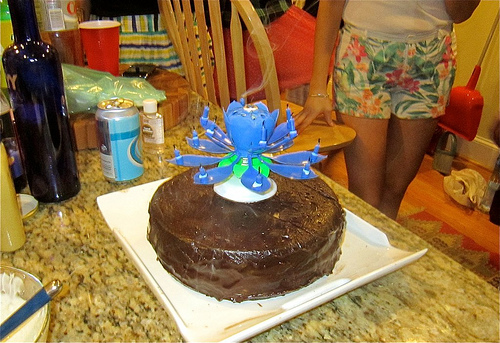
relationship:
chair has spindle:
[159, 1, 357, 155] [208, 0, 230, 114]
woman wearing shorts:
[293, 0, 480, 221] [333, 23, 458, 119]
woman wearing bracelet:
[293, 0, 480, 221] [306, 93, 329, 96]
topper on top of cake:
[166, 98, 328, 203] [148, 159, 344, 303]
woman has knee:
[293, 0, 480, 221] [387, 182, 404, 202]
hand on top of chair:
[290, 97, 334, 133] [159, 1, 357, 155]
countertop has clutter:
[1, 90, 499, 343] [1, 1, 166, 343]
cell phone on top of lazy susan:
[121, 64, 155, 78] [67, 64, 191, 150]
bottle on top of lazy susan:
[44, 0, 83, 67] [67, 64, 191, 150]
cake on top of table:
[148, 159, 344, 303] [1, 90, 499, 343]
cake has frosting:
[148, 159, 344, 303] [149, 158, 346, 302]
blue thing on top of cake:
[166, 98, 328, 203] [148, 159, 344, 303]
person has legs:
[293, 0, 480, 221] [335, 110, 438, 219]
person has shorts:
[293, 0, 480, 221] [333, 23, 458, 119]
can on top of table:
[96, 97, 141, 183] [1, 90, 499, 343]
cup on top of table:
[80, 21, 120, 78] [1, 90, 499, 343]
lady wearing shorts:
[293, 0, 480, 221] [333, 23, 458, 119]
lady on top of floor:
[293, 0, 480, 221] [311, 83, 500, 256]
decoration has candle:
[166, 98, 328, 203] [172, 145, 178, 158]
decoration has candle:
[166, 98, 328, 203] [193, 128, 196, 136]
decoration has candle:
[166, 98, 328, 203] [258, 168, 260, 176]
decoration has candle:
[166, 98, 328, 203] [307, 157, 311, 167]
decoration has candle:
[166, 98, 328, 203] [285, 104, 290, 119]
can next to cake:
[96, 97, 141, 183] [148, 159, 344, 303]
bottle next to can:
[140, 99, 164, 154] [96, 97, 141, 183]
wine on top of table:
[2, 0, 80, 202] [1, 90, 499, 343]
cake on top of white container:
[148, 159, 344, 303] [97, 175, 428, 342]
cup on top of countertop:
[80, 21, 120, 78] [1, 90, 499, 343]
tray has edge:
[97, 175, 428, 342] [114, 229, 186, 333]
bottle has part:
[44, 0, 83, 67] [45, 0, 79, 30]